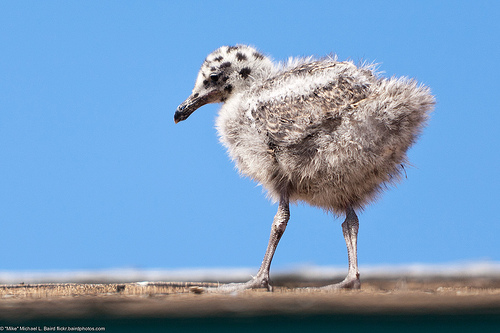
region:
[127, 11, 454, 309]
a cute little bird.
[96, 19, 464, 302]
an interesting little bird.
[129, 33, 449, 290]
a spotted little bird.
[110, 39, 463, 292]
a unique little bird.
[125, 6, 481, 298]
a special looking little bird.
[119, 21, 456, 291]
a special bird out in daylight.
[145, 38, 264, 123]
head of a bird.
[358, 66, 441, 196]
tail end of a bird.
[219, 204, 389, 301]
legs of a little bird.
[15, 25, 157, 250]
part of a clear blue sky.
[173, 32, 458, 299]
a young bird of an exotic species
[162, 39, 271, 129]
the spotted head of a young exotic bird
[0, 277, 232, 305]
a fragment of ground that a young bird is standing on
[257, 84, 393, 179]
the texture of fuzz on a young exotic bird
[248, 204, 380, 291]
the frail legs of a young exotic bird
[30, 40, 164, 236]
the sky behind a young exotic bird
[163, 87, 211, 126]
black beak of a young exotic bird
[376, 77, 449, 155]
slightly pointed tail of a young exotic bird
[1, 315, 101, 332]
credits of the person who took the photo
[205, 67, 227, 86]
the eye of a young exotic bird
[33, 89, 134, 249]
this is the sky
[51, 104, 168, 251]
the sky is blue in colour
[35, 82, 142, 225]
the sky is clear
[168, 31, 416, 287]
this is a baby bird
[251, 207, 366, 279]
the bird's feet are apart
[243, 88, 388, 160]
the feathers are white in color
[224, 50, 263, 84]
the head has black spots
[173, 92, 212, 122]
this is the bird's beak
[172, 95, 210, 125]
the beak is small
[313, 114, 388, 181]
the feathers are kinky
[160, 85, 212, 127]
the bird's beak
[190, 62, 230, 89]
the bird's eye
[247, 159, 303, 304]
the bird's left leg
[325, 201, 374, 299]
the bird's right leg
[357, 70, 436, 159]
the bird's bushy tail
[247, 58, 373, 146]
the bird's left wing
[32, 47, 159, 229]
the clear blue sky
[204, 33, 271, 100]
black spots on the birds head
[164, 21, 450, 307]
a black and white fluffy bird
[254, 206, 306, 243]
the bird's left knee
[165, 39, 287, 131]
head of bird is polka dotted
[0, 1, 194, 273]
vast blue sky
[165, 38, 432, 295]
a baby bird stands on the ground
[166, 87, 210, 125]
beak a of bird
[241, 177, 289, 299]
the leg of a baby bird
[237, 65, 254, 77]
black spot on a bird's head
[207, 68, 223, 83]
bird's eye is open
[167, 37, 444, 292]
baby bird is not yet flying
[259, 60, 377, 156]
wing of a bird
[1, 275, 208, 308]
dirt on the ground